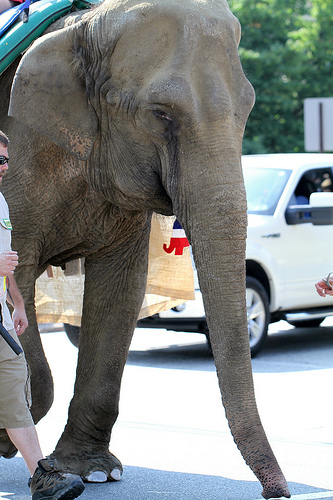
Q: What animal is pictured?
A: An elephant.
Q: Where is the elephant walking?
A: On the street.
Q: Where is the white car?
A: Behind the elephant.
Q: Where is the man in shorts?
A: To the left of the elephant.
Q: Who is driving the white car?
A: A person.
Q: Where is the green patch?
A: On the man's shirt.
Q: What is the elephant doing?
A: Walking.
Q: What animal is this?
A: Elephant.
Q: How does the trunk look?
A: Long.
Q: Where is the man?
A: Beside the elephant.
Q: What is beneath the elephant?
A: Pavement.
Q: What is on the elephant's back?
A: Saddle.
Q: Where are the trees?
A: In the distance.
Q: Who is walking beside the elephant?
A: A man.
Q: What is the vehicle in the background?
A: A car.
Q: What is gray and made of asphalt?
A: The road.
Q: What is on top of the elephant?
A: A seat.